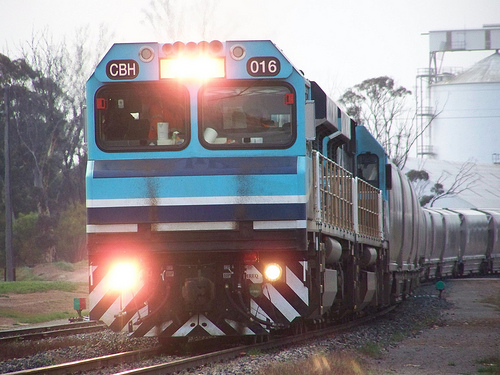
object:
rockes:
[0, 354, 19, 370]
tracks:
[0, 339, 204, 375]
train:
[82, 39, 498, 357]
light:
[108, 258, 141, 292]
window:
[94, 82, 190, 152]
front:
[84, 41, 309, 339]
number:
[249, 57, 279, 74]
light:
[171, 49, 212, 84]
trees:
[3, 32, 86, 264]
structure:
[412, 22, 498, 164]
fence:
[15, 231, 86, 267]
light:
[261, 260, 283, 283]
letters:
[109, 63, 119, 76]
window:
[195, 77, 299, 151]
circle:
[434, 280, 446, 292]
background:
[0, 0, 500, 159]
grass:
[0, 276, 88, 296]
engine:
[83, 35, 390, 338]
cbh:
[108, 62, 137, 78]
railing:
[312, 150, 385, 245]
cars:
[441, 207, 489, 278]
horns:
[207, 40, 223, 55]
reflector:
[72, 297, 87, 311]